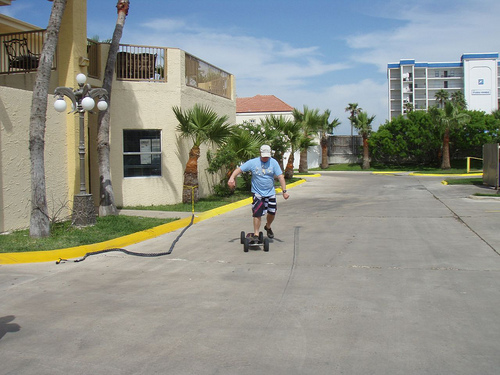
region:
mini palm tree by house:
[174, 102, 221, 208]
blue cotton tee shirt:
[240, 156, 282, 199]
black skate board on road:
[238, 227, 271, 253]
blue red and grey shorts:
[252, 192, 278, 219]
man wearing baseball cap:
[226, 146, 290, 248]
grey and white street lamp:
[53, 74, 108, 228]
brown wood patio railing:
[2, 31, 239, 96]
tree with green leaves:
[375, 109, 492, 165]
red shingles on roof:
[235, 94, 292, 113]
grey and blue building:
[386, 53, 498, 110]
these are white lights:
[48, 68, 115, 126]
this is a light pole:
[53, 70, 110, 239]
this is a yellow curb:
[6, 232, 147, 264]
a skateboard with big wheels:
[230, 224, 285, 261]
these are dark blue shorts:
[251, 185, 279, 216]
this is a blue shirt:
[237, 150, 283, 205]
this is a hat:
[253, 134, 275, 164]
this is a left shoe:
[261, 220, 281, 247]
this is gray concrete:
[357, 279, 393, 324]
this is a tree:
[167, 105, 228, 208]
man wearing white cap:
[251, 135, 285, 183]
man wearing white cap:
[212, 120, 290, 161]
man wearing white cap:
[247, 141, 294, 216]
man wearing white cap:
[234, 92, 289, 190]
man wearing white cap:
[200, 92, 277, 199]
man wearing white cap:
[190, 52, 311, 206]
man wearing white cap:
[220, 124, 290, 284]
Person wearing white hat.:
[256, 144, 273, 158]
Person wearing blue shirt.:
[243, 159, 315, 194]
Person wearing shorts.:
[233, 190, 310, 217]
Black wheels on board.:
[231, 225, 278, 270]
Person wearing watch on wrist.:
[272, 189, 302, 204]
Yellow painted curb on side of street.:
[91, 235, 173, 249]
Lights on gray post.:
[60, 77, 114, 110]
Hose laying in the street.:
[48, 248, 103, 274]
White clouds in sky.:
[280, 57, 362, 114]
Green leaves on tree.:
[391, 116, 417, 152]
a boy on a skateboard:
[222, 133, 299, 258]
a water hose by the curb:
[45, 161, 207, 293]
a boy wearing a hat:
[244, 137, 281, 177]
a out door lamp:
[46, 58, 117, 248]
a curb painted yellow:
[10, 195, 252, 276]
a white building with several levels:
[375, 60, 476, 135]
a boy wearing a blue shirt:
[241, 136, 295, 226]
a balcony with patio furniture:
[1, 26, 233, 88]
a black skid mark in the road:
[285, 207, 302, 306]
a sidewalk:
[93, 203, 170, 238]